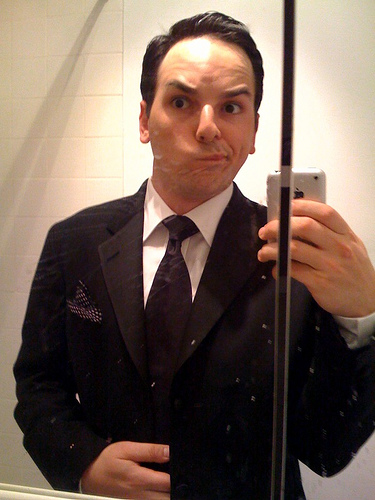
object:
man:
[96, 41, 295, 335]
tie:
[158, 216, 204, 320]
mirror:
[238, 267, 277, 377]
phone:
[269, 156, 324, 209]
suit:
[82, 221, 294, 438]